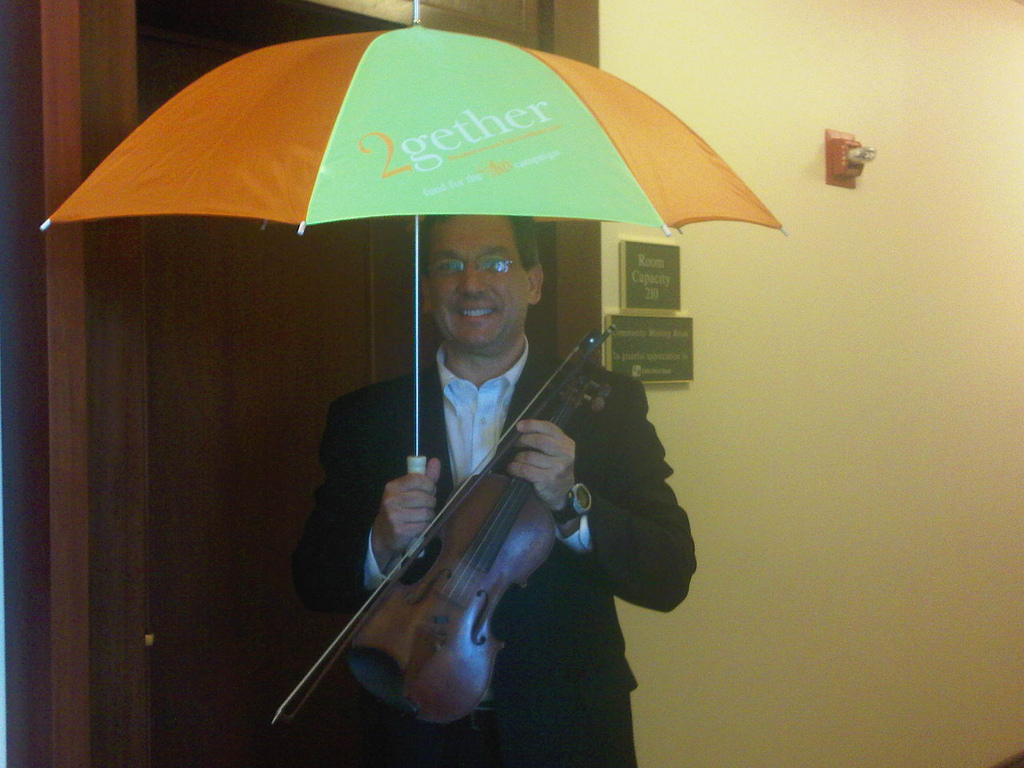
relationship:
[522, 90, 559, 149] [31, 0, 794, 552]
letter on umbrella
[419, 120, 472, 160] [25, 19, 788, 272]
letter on umbrella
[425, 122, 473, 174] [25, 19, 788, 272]
letter on umbrella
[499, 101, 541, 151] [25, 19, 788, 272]
letter on umbrella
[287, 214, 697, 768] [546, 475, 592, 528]
man wearing watch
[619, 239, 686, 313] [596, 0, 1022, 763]
plaque on wall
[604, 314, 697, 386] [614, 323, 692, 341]
placard with lettering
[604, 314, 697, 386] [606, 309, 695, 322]
placard with frame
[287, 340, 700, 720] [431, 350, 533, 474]
blazer with shirt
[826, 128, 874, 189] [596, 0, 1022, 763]
alarm on wall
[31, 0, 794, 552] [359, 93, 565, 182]
umbrella has text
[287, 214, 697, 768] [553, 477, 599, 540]
man wearing a watch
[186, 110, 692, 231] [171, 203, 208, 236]
umbrella green and orange in color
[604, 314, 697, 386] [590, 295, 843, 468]
placard on wall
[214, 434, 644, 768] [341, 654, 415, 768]
violin brown in color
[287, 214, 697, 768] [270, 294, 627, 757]
man holding violin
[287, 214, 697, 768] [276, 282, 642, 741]
man with violin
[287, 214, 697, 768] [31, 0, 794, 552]
man holding umbrella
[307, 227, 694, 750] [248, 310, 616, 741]
man holding violin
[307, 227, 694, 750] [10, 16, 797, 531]
man with umbrella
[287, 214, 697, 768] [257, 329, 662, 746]
man holding violin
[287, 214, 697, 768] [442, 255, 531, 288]
man in glasses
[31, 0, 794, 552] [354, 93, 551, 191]
umbrella with logo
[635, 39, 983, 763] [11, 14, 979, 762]
wall on building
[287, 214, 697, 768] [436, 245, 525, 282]
man wearing glasses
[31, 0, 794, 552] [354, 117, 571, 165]
umbrella with letters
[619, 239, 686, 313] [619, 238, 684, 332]
plaque with lettering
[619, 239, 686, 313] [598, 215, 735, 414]
plaque with frame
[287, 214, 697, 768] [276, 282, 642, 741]
man holding violin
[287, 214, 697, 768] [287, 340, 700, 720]
man wearing blazer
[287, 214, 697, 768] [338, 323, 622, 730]
man holding violin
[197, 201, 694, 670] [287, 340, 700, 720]
man with blazer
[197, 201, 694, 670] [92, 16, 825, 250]
man with umbrella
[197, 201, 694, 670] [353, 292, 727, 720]
man with violin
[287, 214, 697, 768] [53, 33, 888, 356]
man with umbrella